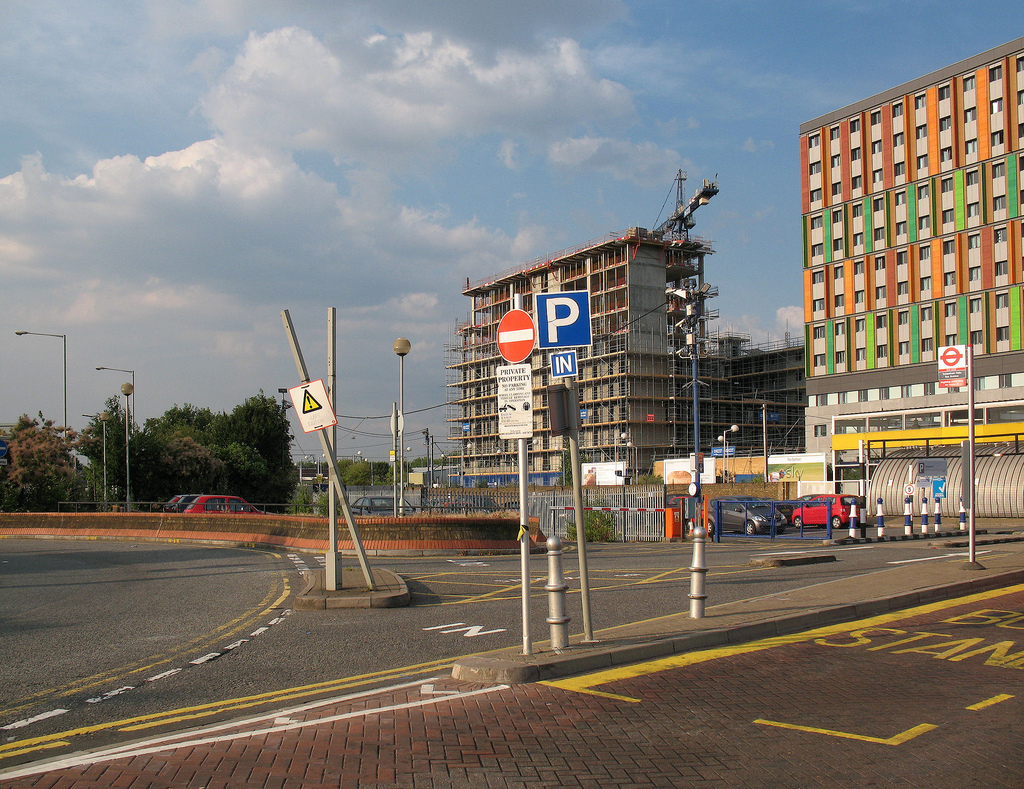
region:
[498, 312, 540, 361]
the sign is the color red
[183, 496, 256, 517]
the car is the color red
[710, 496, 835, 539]
the fence is the color blue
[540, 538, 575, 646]
the pole is the color silver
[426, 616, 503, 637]
the word "IN" is the color white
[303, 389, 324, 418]
the triangle is the color yellow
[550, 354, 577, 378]
the sign is the color blue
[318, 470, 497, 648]
A person eating a orange.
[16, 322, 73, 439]
a tall street light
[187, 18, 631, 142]
a large white cloud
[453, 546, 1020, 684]
a long concrete sidewalk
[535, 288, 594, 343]
a blue and white sign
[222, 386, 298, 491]
a large green tree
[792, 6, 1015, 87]
a blue sky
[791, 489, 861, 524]
a small red car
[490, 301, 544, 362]
a red and white sign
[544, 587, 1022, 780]
yellow street markings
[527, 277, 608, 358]
blue and white sign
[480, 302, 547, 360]
red circular sign with white stripe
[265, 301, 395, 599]
bent silver post on street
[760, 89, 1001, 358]
colorful front of building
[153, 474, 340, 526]
cars parked in the parking lot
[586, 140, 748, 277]
large construction equipment on top of building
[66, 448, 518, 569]
red and green barrier at side of road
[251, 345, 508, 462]
long electrical grid at side of buildings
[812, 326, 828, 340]
A window on a building.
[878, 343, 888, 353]
A window on a building.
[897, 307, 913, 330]
A window on a building.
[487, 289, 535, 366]
round do not enter sign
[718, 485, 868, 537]
two cars parked in front of building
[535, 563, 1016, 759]
parking spot reserved for buses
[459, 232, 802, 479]
building under construction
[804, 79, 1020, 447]
apartment with orange and green trim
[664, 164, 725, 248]
sky crane over building under construction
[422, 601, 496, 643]
word in painted on road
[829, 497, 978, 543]
line of post keeping traffic off median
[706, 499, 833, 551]
blue gate in front of parking area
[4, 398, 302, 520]
small area of trees